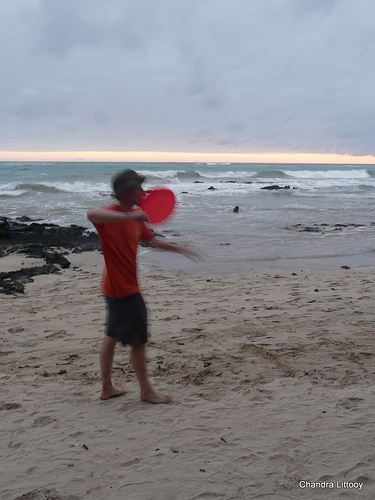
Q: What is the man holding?
A: A frisbee.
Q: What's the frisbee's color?
A: Red.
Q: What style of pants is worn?
A: Shorts.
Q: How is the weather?
A: Overcast.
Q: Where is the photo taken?
A: At the beach.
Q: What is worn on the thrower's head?
A: A hat.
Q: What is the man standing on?
A: Sand.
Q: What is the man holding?
A: Frisbee.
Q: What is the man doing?
A: Throwing a frisbee.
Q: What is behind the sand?
A: Ocean.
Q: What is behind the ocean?
A: Sky.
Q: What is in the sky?
A: Clouds.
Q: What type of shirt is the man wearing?
A: Short sleeved t shirt.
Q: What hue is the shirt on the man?
A: Orange.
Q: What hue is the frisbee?
A: Red.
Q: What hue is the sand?
A: Tan.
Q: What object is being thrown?
A: A frisbee.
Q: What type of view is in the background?
A: The ocean.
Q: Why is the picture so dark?
A: It's sunset.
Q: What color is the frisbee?
A: Red.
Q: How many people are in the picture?
A: One.